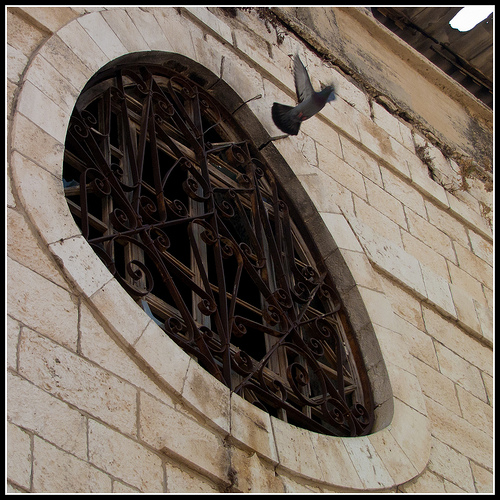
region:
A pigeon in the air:
[303, 93, 315, 113]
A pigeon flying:
[299, 79, 308, 98]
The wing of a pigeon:
[298, 79, 305, 94]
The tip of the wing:
[294, 55, 297, 58]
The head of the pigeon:
[326, 86, 333, 92]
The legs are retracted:
[298, 112, 305, 120]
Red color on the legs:
[297, 113, 306, 120]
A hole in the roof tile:
[461, 13, 476, 25]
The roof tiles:
[420, 15, 445, 27]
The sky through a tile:
[465, 11, 480, 21]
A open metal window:
[97, 82, 367, 402]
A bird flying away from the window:
[279, 57, 356, 127]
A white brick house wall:
[4, 359, 131, 480]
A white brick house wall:
[137, 382, 274, 492]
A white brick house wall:
[312, 439, 426, 486]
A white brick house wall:
[422, 331, 489, 481]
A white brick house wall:
[347, 209, 487, 324]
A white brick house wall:
[347, 101, 496, 204]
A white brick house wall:
[222, 9, 304, 78]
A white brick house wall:
[2, 23, 68, 234]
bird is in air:
[304, 71, 334, 115]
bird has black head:
[302, 64, 360, 119]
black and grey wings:
[281, 51, 314, 101]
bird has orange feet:
[295, 99, 311, 129]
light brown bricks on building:
[343, 163, 479, 327]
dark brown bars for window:
[115, 94, 325, 359]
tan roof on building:
[387, 1, 488, 78]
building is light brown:
[36, 36, 411, 473]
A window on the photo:
[107, 123, 317, 349]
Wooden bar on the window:
[96, 164, 230, 281]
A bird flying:
[276, 61, 337, 138]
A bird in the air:
[265, 52, 342, 138]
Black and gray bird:
[245, 64, 360, 146]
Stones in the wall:
[350, 159, 429, 277]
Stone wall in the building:
[405, 268, 462, 385]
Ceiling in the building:
[405, 26, 462, 74]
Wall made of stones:
[375, 137, 440, 246]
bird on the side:
[272, 58, 331, 138]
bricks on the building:
[22, 390, 172, 484]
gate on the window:
[138, 220, 282, 337]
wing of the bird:
[286, 53, 311, 103]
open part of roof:
[445, 8, 487, 45]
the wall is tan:
[32, 398, 158, 465]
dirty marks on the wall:
[190, 440, 245, 478]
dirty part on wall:
[452, 105, 480, 160]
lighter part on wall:
[353, 420, 389, 487]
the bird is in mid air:
[269, 54, 338, 133]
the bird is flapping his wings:
[273, 53, 337, 140]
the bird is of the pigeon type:
[276, 55, 333, 136]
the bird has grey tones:
[267, 53, 336, 135]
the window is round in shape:
[56, 45, 397, 433]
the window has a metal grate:
[68, 47, 391, 444]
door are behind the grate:
[85, 80, 367, 437]